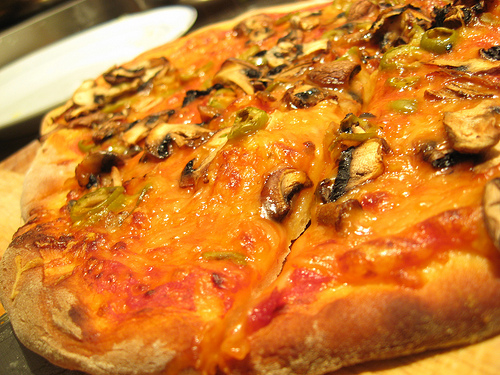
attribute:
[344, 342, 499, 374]
cuttingboard — wooden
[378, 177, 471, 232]
cheese — dark yellow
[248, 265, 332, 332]
sauce — red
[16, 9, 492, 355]
pizza — green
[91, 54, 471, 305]
pizza — baked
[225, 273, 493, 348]
crust — browned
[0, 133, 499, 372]
pizza crust — thick, brown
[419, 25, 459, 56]
olive — green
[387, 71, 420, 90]
olive — green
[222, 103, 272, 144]
olive — green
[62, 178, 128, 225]
olive — green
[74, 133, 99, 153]
olive — green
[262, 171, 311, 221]
mushroom — burnt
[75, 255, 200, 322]
sauce — red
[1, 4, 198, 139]
plate — empty, white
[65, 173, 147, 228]
peppers — green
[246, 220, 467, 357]
crust — burned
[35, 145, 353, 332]
cheese — yellow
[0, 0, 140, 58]
backsplash — steel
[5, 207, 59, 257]
crust — burned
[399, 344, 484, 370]
surface — tan